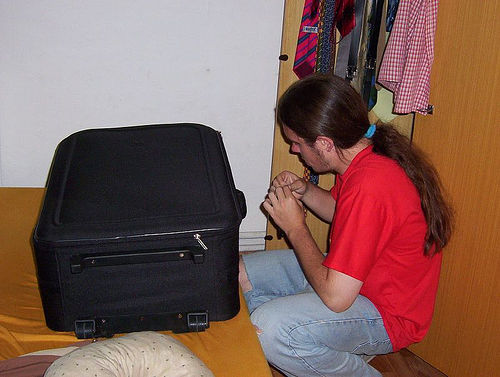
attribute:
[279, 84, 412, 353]
man — white, kneeling, squatting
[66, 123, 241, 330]
luggage — blue, black, large, metal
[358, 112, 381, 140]
band — blue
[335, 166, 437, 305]
shirt — red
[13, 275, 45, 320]
table — brown, wood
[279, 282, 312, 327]
jeans — blue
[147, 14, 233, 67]
wall — white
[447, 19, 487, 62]
door — open